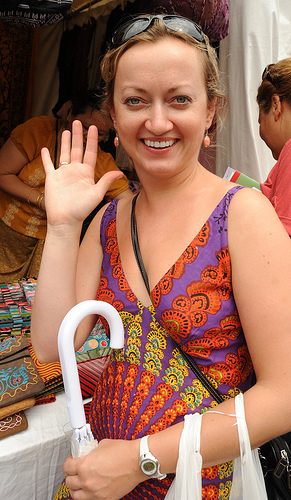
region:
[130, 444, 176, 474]
white wristwatch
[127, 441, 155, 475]
white wristwatch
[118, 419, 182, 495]
white wristwatch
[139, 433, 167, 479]
White watch on a woman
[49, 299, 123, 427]
White handle of an umbrella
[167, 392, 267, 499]
White plastic bag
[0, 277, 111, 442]
Different types of fabric on a table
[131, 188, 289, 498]
All black purse with a woman wearing it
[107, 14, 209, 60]
Black sunglasses on a woman's head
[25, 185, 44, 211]
Gold ring bracelets on a woman's arm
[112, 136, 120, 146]
Red and silver earring on a woman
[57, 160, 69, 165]
Silver colored wedding ring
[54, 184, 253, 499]
Purple, Red, yellow, blue and black dress on a woman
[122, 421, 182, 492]
a white watch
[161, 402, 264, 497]
a white shopping bag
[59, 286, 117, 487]
a white umbrella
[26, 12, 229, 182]
a woman smiling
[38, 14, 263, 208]
a woman waving her hand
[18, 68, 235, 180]
a woman wearing a ring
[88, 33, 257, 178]
a woman wearing earrings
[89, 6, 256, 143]
a woman with sunglasses on her head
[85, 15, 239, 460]
a woman wearing a dress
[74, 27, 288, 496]
a woman wearing a black purse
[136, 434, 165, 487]
white watch on left wrist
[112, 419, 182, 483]
white wristwatch on hand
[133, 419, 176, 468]
white wristwatch on hand